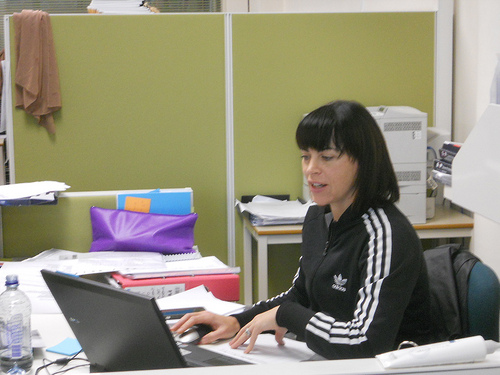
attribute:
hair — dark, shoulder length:
[295, 97, 401, 214]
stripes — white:
[306, 205, 392, 342]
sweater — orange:
[13, 8, 64, 136]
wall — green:
[3, 10, 441, 306]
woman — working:
[168, 98, 434, 360]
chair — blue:
[423, 245, 499, 343]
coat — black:
[423, 242, 482, 346]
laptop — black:
[40, 268, 253, 373]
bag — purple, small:
[88, 204, 198, 255]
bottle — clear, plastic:
[0, 273, 34, 374]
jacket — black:
[229, 195, 433, 361]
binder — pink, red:
[106, 268, 241, 301]